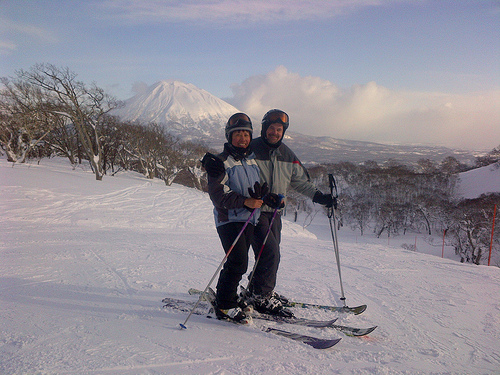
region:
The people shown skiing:
[160, 105, 385, 352]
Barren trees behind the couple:
[0, 61, 211, 188]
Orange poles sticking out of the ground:
[352, 203, 498, 266]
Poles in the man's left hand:
[320, 168, 348, 304]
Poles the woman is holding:
[176, 190, 288, 335]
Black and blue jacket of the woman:
[205, 149, 271, 225]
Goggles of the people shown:
[223, 107, 293, 134]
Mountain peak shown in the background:
[103, 76, 266, 148]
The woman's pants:
[210, 217, 252, 310]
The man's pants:
[248, 208, 284, 298]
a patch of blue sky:
[403, 22, 452, 58]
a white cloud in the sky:
[308, 72, 377, 116]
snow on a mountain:
[151, 72, 211, 104]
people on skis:
[186, 93, 388, 348]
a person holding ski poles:
[230, 186, 287, 304]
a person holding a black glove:
[241, 177, 271, 213]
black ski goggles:
[221, 111, 257, 125]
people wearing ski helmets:
[211, 100, 296, 146]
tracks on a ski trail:
[65, 236, 130, 321]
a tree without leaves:
[52, 74, 99, 123]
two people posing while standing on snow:
[190, 97, 340, 362]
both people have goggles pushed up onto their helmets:
[222, 100, 292, 132]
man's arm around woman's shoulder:
[193, 108, 300, 177]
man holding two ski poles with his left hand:
[312, 161, 360, 313]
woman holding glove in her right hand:
[231, 171, 267, 216]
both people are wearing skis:
[156, 270, 386, 359]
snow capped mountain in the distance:
[113, 73, 255, 138]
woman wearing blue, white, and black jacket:
[200, 140, 270, 222]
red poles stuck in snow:
[356, 200, 496, 268]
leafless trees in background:
[5, 62, 197, 209]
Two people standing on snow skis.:
[149, 100, 399, 361]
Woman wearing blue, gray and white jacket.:
[198, 143, 265, 227]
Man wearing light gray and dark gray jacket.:
[256, 136, 316, 213]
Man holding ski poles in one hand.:
[324, 168, 364, 307]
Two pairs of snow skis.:
[156, 283, 384, 351]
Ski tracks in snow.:
[59, 183, 198, 250]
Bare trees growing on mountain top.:
[8, 88, 188, 195]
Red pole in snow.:
[478, 202, 499, 274]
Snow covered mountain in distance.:
[108, 77, 260, 136]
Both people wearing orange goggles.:
[226, 107, 291, 129]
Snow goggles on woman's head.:
[225, 109, 255, 131]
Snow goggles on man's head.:
[263, 111, 292, 127]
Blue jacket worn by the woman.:
[217, 158, 266, 222]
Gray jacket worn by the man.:
[262, 147, 297, 214]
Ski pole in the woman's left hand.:
[172, 188, 247, 336]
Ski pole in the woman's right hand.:
[242, 191, 273, 318]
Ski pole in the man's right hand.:
[321, 177, 353, 301]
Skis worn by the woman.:
[171, 298, 339, 353]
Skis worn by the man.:
[274, 290, 376, 335]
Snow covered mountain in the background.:
[114, 73, 252, 150]